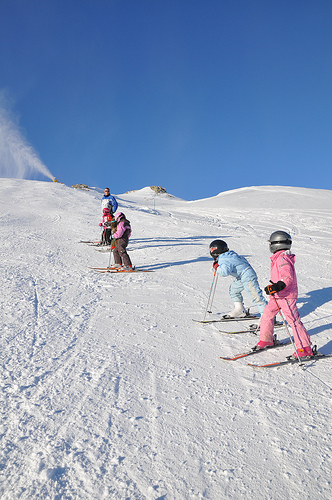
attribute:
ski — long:
[245, 353, 331, 367]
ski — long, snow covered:
[220, 342, 285, 363]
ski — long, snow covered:
[219, 328, 262, 339]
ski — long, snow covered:
[193, 317, 261, 325]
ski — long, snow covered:
[92, 268, 156, 276]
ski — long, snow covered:
[88, 264, 122, 271]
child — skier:
[108, 213, 133, 271]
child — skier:
[250, 231, 316, 361]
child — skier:
[208, 240, 270, 319]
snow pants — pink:
[257, 296, 312, 347]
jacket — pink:
[266, 251, 298, 298]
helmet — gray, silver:
[269, 231, 292, 252]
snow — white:
[0, 93, 55, 183]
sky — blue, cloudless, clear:
[1, 0, 331, 201]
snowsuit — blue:
[214, 251, 268, 320]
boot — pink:
[287, 346, 314, 360]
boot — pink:
[254, 343, 272, 352]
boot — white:
[224, 303, 247, 319]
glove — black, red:
[265, 279, 286, 295]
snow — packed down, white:
[0, 180, 332, 499]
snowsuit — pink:
[260, 249, 313, 350]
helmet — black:
[208, 240, 228, 257]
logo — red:
[208, 245, 217, 253]